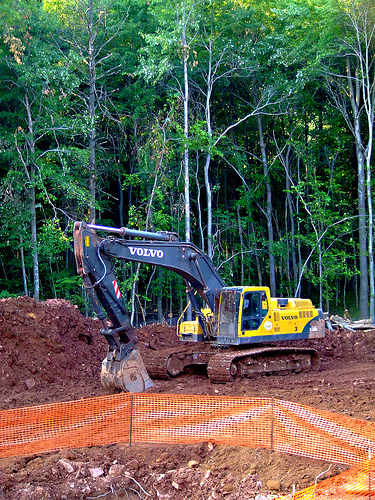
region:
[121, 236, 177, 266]
Volvo on the tractor.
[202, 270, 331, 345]
The tractor is mostly yellow.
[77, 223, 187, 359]
Black on the tractor.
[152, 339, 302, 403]
Dirt on the tracks.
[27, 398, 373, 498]
The fence is orange.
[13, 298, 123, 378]
A large dirt pile.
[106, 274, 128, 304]
Red and white sticker on the tractor.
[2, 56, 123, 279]
The trees are green.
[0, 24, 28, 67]
Brown chunk of leaves.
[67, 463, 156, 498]
Roots in the ground.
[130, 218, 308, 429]
a bulldozer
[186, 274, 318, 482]
a bulldozer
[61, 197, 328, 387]
a large black and yellow volvo tractor.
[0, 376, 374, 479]
an orange mesh fence.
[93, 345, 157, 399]
a scoop on a tractor.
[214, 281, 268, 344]
a cag inside of a tractor.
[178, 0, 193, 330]
a tall tree with lots of leaves.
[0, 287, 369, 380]
a pile of loose dirt.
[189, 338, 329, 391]
a tread on a tractor.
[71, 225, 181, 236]
a hydraulic on a tractor.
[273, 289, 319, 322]
an engine on a tractor.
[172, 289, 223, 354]
the front of a tractor.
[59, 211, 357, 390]
backhoe made by volvo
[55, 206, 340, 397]
yellow and black backhoe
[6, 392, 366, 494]
orange safety fence around hole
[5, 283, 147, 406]
pile of dirt dug out of hole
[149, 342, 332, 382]
machine sitting on tracks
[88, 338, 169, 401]
bucket on the backhoe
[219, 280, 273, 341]
cab where driver sits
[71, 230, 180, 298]
hydraulic hoses on backhoe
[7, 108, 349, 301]
thick stand of trees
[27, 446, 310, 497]
hole with rocks in it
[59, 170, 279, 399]
a bulldozer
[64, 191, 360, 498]
a bulldozer